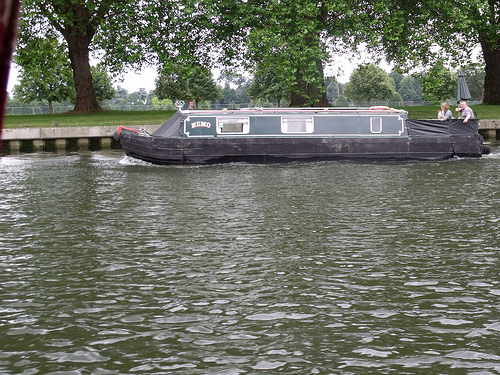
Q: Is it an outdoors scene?
A: Yes, it is outdoors.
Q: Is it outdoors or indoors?
A: It is outdoors.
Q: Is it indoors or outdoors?
A: It is outdoors.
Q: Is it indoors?
A: No, it is outdoors.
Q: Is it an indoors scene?
A: No, it is outdoors.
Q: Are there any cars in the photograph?
A: No, there are no cars.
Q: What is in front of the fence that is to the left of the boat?
A: The tree is in front of the fence.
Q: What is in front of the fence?
A: The tree is in front of the fence.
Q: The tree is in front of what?
A: The tree is in front of the fence.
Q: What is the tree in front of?
A: The tree is in front of the fence.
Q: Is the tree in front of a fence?
A: Yes, the tree is in front of a fence.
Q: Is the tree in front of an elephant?
A: No, the tree is in front of a fence.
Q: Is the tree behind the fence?
A: No, the tree is in front of the fence.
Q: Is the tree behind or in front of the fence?
A: The tree is in front of the fence.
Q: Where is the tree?
A: The tree is in the park.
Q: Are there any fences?
A: Yes, there is a fence.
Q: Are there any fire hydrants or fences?
A: Yes, there is a fence.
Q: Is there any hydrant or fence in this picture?
A: Yes, there is a fence.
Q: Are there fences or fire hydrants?
A: Yes, there is a fence.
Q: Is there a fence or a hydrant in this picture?
A: Yes, there is a fence.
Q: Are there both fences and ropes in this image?
A: No, there is a fence but no ropes.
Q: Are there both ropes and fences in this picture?
A: No, there is a fence but no ropes.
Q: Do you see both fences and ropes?
A: No, there is a fence but no ropes.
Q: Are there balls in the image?
A: No, there are no balls.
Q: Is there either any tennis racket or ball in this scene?
A: No, there are no balls or rackets.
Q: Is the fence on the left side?
A: Yes, the fence is on the left of the image.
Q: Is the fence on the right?
A: No, the fence is on the left of the image.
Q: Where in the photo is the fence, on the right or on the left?
A: The fence is on the left of the image.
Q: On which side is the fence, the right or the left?
A: The fence is on the left of the image.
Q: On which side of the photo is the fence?
A: The fence is on the left of the image.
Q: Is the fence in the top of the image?
A: Yes, the fence is in the top of the image.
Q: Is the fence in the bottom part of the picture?
A: No, the fence is in the top of the image.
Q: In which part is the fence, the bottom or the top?
A: The fence is in the top of the image.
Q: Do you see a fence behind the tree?
A: Yes, there is a fence behind the tree.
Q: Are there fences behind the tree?
A: Yes, there is a fence behind the tree.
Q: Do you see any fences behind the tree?
A: Yes, there is a fence behind the tree.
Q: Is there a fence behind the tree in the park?
A: Yes, there is a fence behind the tree.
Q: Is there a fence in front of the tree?
A: No, the fence is behind the tree.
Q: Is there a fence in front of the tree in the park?
A: No, the fence is behind the tree.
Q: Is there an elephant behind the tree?
A: No, there is a fence behind the tree.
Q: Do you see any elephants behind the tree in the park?
A: No, there is a fence behind the tree.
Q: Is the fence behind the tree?
A: Yes, the fence is behind the tree.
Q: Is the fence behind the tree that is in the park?
A: Yes, the fence is behind the tree.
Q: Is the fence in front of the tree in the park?
A: No, the fence is behind the tree.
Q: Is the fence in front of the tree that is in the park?
A: No, the fence is behind the tree.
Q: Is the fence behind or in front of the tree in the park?
A: The fence is behind the tree.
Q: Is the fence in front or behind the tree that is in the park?
A: The fence is behind the tree.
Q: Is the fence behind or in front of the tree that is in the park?
A: The fence is behind the tree.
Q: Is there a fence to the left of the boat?
A: Yes, there is a fence to the left of the boat.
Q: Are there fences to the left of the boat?
A: Yes, there is a fence to the left of the boat.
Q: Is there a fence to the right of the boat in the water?
A: No, the fence is to the left of the boat.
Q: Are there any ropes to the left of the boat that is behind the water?
A: No, there is a fence to the left of the boat.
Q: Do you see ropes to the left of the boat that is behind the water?
A: No, there is a fence to the left of the boat.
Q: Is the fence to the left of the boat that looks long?
A: Yes, the fence is to the left of the boat.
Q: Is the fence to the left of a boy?
A: No, the fence is to the left of the boat.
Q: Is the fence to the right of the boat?
A: No, the fence is to the left of the boat.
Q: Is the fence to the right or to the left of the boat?
A: The fence is to the left of the boat.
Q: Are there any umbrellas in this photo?
A: Yes, there is an umbrella.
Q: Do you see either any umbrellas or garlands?
A: Yes, there is an umbrella.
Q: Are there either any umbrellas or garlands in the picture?
A: Yes, there is an umbrella.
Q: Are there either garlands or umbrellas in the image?
A: Yes, there is an umbrella.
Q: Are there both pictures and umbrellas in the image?
A: No, there is an umbrella but no pictures.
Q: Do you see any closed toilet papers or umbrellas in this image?
A: Yes, there is a closed umbrella.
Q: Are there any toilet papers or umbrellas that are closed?
A: Yes, the umbrella is closed.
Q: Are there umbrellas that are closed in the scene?
A: Yes, there is a closed umbrella.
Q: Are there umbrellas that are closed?
A: Yes, there is an umbrella that is closed.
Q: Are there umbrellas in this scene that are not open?
A: Yes, there is an closed umbrella.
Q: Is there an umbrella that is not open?
A: Yes, there is an closed umbrella.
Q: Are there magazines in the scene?
A: No, there are no magazines.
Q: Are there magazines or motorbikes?
A: No, there are no magazines or motorbikes.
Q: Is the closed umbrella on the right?
A: Yes, the umbrella is on the right of the image.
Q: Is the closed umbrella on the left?
A: No, the umbrella is on the right of the image.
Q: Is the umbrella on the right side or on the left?
A: The umbrella is on the right of the image.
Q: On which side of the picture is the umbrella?
A: The umbrella is on the right of the image.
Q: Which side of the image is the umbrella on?
A: The umbrella is on the right of the image.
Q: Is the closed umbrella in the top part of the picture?
A: Yes, the umbrella is in the top of the image.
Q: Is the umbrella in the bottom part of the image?
A: No, the umbrella is in the top of the image.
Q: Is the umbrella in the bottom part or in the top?
A: The umbrella is in the top of the image.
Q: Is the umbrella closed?
A: Yes, the umbrella is closed.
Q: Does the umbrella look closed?
A: Yes, the umbrella is closed.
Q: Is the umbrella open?
A: No, the umbrella is closed.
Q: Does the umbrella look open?
A: No, the umbrella is closed.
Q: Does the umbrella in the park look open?
A: No, the umbrella is closed.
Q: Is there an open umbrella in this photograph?
A: No, there is an umbrella but it is closed.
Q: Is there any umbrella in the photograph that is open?
A: No, there is an umbrella but it is closed.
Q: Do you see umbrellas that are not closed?
A: No, there is an umbrella but it is closed.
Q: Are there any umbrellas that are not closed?
A: No, there is an umbrella but it is closed.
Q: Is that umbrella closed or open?
A: The umbrella is closed.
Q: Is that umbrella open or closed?
A: The umbrella is closed.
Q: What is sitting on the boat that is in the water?
A: The umbrella is sitting on the boat.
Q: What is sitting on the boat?
A: The umbrella is sitting on the boat.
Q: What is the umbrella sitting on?
A: The umbrella is sitting on the boat.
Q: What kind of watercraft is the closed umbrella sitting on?
A: The umbrella is sitting on the boat.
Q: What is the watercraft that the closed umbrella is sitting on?
A: The watercraft is a boat.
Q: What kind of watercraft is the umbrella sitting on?
A: The umbrella is sitting on the boat.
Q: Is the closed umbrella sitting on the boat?
A: Yes, the umbrella is sitting on the boat.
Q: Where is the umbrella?
A: The umbrella is in the park.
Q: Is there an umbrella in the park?
A: Yes, there is an umbrella in the park.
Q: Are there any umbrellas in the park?
A: Yes, there is an umbrella in the park.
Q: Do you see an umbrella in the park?
A: Yes, there is an umbrella in the park.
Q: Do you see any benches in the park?
A: No, there is an umbrella in the park.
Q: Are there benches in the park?
A: No, there is an umbrella in the park.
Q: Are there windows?
A: Yes, there is a window.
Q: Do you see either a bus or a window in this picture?
A: Yes, there is a window.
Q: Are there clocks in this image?
A: No, there are no clocks.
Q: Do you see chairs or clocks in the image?
A: No, there are no clocks or chairs.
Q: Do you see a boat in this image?
A: Yes, there is a boat.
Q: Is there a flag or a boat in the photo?
A: Yes, there is a boat.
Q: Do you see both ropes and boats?
A: No, there is a boat but no ropes.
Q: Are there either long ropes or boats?
A: Yes, there is a long boat.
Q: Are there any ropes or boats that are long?
A: Yes, the boat is long.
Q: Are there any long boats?
A: Yes, there is a long boat.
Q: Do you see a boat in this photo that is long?
A: Yes, there is a boat that is long.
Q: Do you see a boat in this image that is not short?
A: Yes, there is a long boat.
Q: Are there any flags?
A: No, there are no flags.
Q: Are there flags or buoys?
A: No, there are no flags or buoys.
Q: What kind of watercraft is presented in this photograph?
A: The watercraft is a boat.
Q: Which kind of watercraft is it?
A: The watercraft is a boat.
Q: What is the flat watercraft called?
A: The watercraft is a boat.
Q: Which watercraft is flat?
A: The watercraft is a boat.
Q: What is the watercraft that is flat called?
A: The watercraft is a boat.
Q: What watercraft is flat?
A: The watercraft is a boat.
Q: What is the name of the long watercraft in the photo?
A: The watercraft is a boat.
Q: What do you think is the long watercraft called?
A: The watercraft is a boat.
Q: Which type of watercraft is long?
A: The watercraft is a boat.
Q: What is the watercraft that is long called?
A: The watercraft is a boat.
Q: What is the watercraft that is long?
A: The watercraft is a boat.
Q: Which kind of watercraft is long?
A: The watercraft is a boat.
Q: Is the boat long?
A: Yes, the boat is long.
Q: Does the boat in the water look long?
A: Yes, the boat is long.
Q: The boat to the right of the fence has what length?
A: The boat is long.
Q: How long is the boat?
A: The boat is long.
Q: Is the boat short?
A: No, the boat is long.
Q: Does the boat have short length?
A: No, the boat is long.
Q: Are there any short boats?
A: No, there is a boat but it is long.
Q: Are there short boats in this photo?
A: No, there is a boat but it is long.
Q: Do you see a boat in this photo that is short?
A: No, there is a boat but it is long.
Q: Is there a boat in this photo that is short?
A: No, there is a boat but it is long.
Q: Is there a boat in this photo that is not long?
A: No, there is a boat but it is long.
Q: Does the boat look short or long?
A: The boat is long.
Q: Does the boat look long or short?
A: The boat is long.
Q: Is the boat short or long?
A: The boat is long.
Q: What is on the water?
A: The boat is on the water.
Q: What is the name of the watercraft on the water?
A: The watercraft is a boat.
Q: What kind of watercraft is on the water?
A: The watercraft is a boat.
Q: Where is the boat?
A: The boat is on the water.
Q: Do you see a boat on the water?
A: Yes, there is a boat on the water.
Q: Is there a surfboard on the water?
A: No, there is a boat on the water.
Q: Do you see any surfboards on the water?
A: No, there is a boat on the water.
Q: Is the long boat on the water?
A: Yes, the boat is on the water.